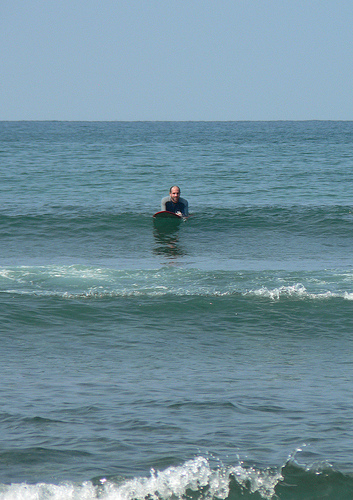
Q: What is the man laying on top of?
A: Surfboard.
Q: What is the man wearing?
A: Wetsuit.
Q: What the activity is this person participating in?
A: Surfing.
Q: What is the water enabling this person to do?
A: Float.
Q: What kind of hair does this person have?
A: Thinning.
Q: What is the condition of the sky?
A: Relatively clear.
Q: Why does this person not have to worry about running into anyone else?
A: Because he's alone.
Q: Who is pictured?
A: A man.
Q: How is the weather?
A: Clear sky.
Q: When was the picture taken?
A: During day hours.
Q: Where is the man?
A: On a surfboard.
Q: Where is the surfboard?
A: In the water.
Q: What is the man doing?
A: Waiting for a wave.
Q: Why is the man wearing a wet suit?
A: To stay warm.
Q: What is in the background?
A: Ocean.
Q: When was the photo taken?
A: Daytime.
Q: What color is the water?
A: Deep blue.